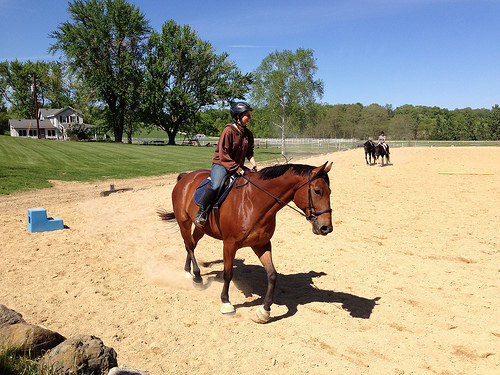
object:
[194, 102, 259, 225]
rider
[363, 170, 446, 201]
dirt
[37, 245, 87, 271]
dirt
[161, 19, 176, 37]
leaves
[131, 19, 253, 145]
trees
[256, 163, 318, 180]
mane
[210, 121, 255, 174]
jacket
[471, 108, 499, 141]
bush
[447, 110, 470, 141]
bush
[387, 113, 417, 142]
bush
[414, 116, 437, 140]
bush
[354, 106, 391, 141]
bush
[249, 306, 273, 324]
shoe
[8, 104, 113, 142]
house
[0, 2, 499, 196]
background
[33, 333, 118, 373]
rock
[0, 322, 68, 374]
rock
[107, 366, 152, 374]
rock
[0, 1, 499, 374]
rural area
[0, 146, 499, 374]
arena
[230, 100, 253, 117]
helmet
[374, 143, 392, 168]
horse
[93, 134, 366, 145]
fence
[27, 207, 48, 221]
step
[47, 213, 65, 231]
step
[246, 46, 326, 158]
trees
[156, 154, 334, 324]
horse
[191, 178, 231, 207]
blanket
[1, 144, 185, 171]
green grass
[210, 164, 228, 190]
blue jeans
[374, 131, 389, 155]
person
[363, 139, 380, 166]
horse